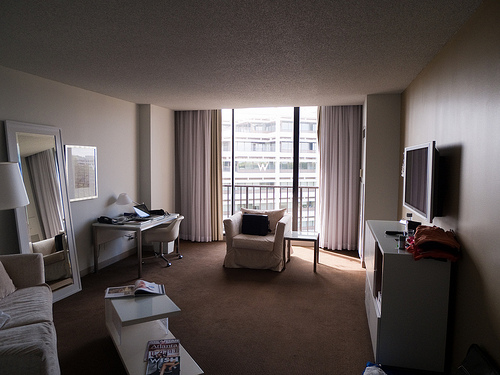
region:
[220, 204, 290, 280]
White chair sitting in center of room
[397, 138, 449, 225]
Flatscreen TV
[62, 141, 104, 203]
Picture hung on the wall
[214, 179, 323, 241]
Safety railing on the balcony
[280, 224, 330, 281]
Small wooden table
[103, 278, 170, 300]
Magazine sitting on a coffee table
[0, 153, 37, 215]
Lampshade of a floor lamp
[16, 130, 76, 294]
Mirror hung on a door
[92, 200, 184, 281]
Table full of objects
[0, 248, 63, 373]
Loveseat in the living room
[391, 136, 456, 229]
A tv is attached to the wall.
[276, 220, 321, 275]
A small end table.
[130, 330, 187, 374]
Magazines are on the coffee table.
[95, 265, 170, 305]
An open book.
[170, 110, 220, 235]
Curtains.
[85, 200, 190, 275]
A desk with items on it.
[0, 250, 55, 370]
A couch.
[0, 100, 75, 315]
A large mirror with a white frame.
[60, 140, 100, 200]
A framed picture on the wall.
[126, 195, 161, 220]
A laptop is on the desk.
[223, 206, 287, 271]
white armchair in front of sliding doors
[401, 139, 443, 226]
flat screen tv on wall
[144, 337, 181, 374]
magazines on coffee table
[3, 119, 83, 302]
large mirror leaning against wall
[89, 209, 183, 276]
desk with rolling chair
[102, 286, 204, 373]
coffee table with magazines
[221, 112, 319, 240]
sliding glass doors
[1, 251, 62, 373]
white sofa beside coffee table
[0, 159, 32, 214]
lampshade beside sofa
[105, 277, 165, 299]
open magazine on table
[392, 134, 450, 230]
flat screen television on wall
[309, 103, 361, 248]
white curtain on window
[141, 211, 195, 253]
white chair under desk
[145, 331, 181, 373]
magazines on white table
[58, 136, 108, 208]
framed picture on wall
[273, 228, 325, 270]
square table next to chair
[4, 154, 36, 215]
white shade on lamp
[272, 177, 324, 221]
railing on edge of balcony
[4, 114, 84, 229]
mirror resting against wall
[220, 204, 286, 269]
chair in living room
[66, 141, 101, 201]
print hanging on wall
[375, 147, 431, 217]
tv mounted on wall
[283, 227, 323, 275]
side table by chair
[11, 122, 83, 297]
floor mirror against wall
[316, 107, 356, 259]
floor length curtains on window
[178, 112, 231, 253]
floor length curtains on window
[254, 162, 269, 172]
hotel logo on window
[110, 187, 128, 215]
lamp on side table